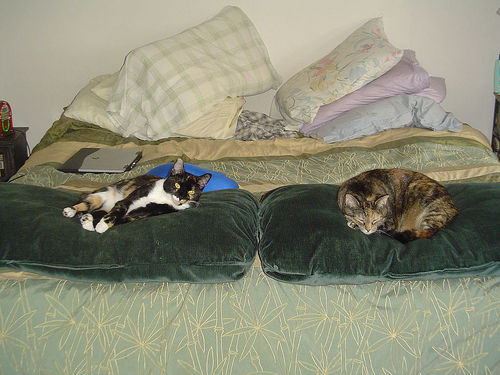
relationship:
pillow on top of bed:
[259, 174, 497, 283] [5, 105, 497, 375]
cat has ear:
[336, 168, 457, 240] [341, 192, 360, 215]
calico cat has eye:
[64, 158, 210, 234] [174, 181, 181, 189]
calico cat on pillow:
[64, 158, 210, 234] [26, 192, 454, 280]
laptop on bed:
[57, 147, 141, 175] [13, 18, 481, 368]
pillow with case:
[274, 18, 404, 131] [278, 14, 399, 108]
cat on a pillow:
[336, 168, 457, 240] [259, 174, 497, 283]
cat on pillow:
[336, 168, 457, 240] [7, 178, 257, 284]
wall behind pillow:
[1, 3, 499, 146] [88, 4, 282, 143]